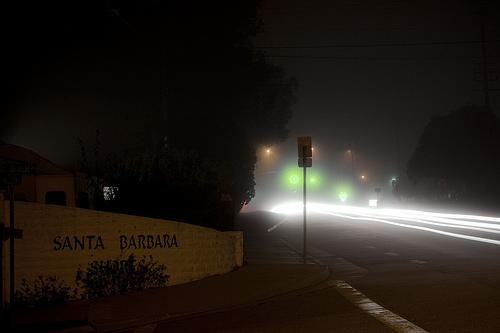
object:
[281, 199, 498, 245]
light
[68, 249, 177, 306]
bush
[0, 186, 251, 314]
sign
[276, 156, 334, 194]
lights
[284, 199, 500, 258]
ground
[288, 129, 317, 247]
post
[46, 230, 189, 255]
sant barbara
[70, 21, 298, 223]
trees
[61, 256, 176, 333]
plants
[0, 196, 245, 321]
wall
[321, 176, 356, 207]
lights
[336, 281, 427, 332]
line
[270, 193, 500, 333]
street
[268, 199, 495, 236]
streaks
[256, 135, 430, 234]
fog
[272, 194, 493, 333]
road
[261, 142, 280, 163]
yellow light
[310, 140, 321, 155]
yellow light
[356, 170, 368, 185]
yellow light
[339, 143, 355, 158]
yellow light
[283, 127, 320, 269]
sign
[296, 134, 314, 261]
street sign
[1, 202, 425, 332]
curb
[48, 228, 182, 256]
name